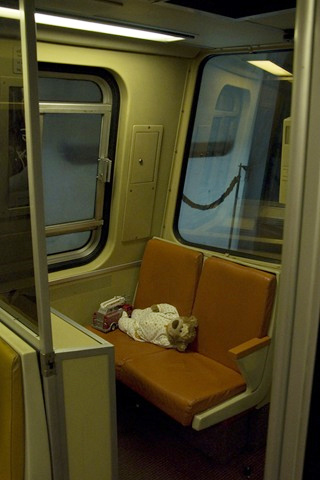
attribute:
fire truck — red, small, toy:
[93, 294, 134, 334]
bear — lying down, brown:
[121, 301, 200, 356]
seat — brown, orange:
[81, 233, 273, 426]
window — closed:
[9, 69, 114, 273]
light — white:
[1, 8, 187, 43]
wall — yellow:
[4, 38, 196, 329]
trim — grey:
[2, 3, 119, 479]